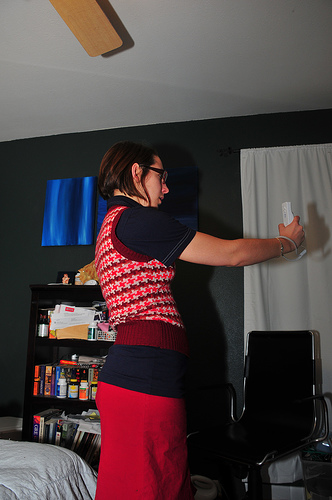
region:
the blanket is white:
[49, 462, 62, 487]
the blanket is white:
[48, 472, 57, 484]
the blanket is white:
[40, 465, 44, 468]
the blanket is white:
[34, 461, 67, 490]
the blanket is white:
[35, 454, 53, 480]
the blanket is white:
[55, 465, 67, 481]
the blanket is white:
[64, 478, 65, 479]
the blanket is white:
[50, 468, 65, 478]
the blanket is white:
[47, 468, 58, 480]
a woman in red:
[126, 344, 211, 491]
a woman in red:
[116, 386, 168, 494]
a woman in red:
[96, 406, 131, 473]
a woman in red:
[124, 429, 172, 493]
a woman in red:
[151, 473, 159, 489]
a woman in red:
[124, 454, 138, 464]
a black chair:
[212, 358, 302, 490]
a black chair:
[239, 363, 283, 454]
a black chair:
[253, 412, 280, 496]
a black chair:
[256, 411, 273, 470]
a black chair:
[261, 389, 279, 465]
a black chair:
[246, 380, 294, 482]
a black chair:
[262, 428, 302, 493]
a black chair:
[226, 390, 262, 485]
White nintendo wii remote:
[272, 200, 312, 249]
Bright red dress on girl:
[71, 369, 207, 498]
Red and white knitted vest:
[83, 198, 169, 338]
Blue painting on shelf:
[24, 178, 129, 255]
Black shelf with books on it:
[15, 264, 153, 443]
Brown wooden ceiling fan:
[50, 2, 156, 80]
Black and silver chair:
[222, 323, 328, 465]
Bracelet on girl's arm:
[264, 230, 307, 269]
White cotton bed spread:
[0, 435, 100, 496]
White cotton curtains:
[213, 134, 329, 346]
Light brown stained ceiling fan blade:
[47, 1, 139, 61]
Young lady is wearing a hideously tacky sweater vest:
[80, 205, 189, 351]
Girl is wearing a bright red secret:
[96, 378, 181, 498]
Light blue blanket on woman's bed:
[2, 439, 94, 497]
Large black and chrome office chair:
[248, 324, 326, 452]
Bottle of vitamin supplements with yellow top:
[68, 374, 79, 400]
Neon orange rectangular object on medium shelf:
[33, 364, 40, 395]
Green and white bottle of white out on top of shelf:
[87, 319, 98, 339]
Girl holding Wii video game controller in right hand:
[261, 199, 308, 261]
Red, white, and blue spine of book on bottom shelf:
[32, 412, 40, 441]